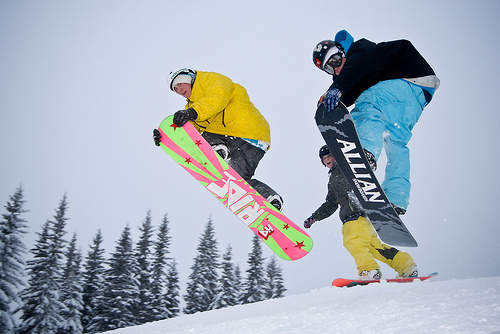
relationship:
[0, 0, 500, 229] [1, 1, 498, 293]
clouds in sky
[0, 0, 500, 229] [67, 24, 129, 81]
clouds in sky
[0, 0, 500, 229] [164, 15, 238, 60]
clouds in sky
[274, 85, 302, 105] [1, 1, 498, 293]
clouds in sky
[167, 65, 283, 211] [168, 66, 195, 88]
person wearing helmet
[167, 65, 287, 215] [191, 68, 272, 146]
person wearing jacket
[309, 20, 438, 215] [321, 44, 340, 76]
person wearing goggles